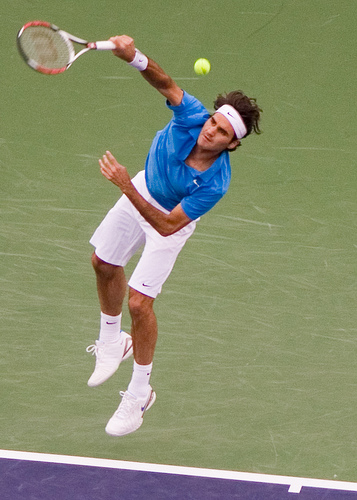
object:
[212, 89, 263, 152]
hair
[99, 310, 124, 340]
socks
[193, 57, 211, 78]
ball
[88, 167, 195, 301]
pants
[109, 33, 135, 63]
hand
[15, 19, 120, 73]
tennis racket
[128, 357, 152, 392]
socks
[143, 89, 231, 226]
shirt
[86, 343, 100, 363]
shoe lace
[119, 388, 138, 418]
shoe lace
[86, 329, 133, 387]
shoe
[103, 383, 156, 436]
shoe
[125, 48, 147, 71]
wristband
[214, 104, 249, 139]
headband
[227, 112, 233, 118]
nike logo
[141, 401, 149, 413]
nike logo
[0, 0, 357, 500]
tennis court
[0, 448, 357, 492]
stripe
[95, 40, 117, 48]
tape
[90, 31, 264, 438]
person